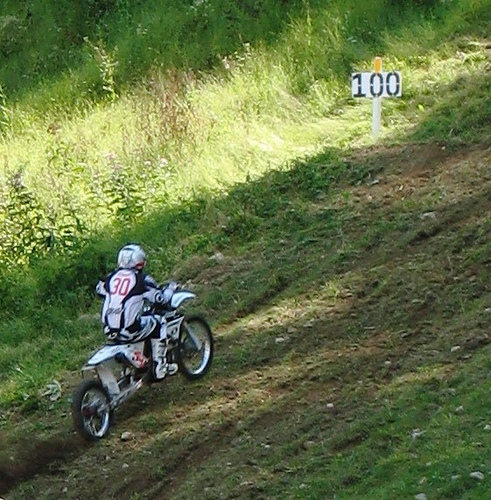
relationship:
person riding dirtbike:
[92, 243, 182, 382] [70, 272, 225, 446]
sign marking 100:
[349, 56, 406, 142] [349, 71, 404, 98]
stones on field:
[417, 207, 439, 223] [0, 123, 490, 498]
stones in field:
[417, 207, 439, 223] [0, 123, 490, 498]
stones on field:
[447, 338, 468, 354] [0, 123, 490, 498]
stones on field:
[469, 468, 489, 483] [0, 123, 490, 498]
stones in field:
[118, 431, 134, 441] [0, 123, 490, 498]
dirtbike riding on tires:
[70, 272, 225, 446] [71, 381, 112, 443]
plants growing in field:
[7, 170, 64, 272] [0, 123, 490, 498]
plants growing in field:
[103, 152, 142, 225] [0, 123, 490, 498]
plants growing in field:
[137, 151, 173, 198] [0, 123, 490, 498]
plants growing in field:
[202, 104, 282, 185] [0, 123, 490, 498]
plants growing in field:
[59, 189, 95, 240] [0, 123, 490, 498]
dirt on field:
[158, 465, 187, 484] [0, 123, 490, 498]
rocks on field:
[383, 359, 390, 365] [0, 123, 490, 498]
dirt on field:
[326, 401, 333, 409] [0, 123, 490, 498]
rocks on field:
[273, 334, 287, 344] [0, 123, 490, 498]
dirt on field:
[408, 237, 420, 250] [0, 123, 490, 498]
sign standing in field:
[349, 56, 406, 142] [1, 1, 490, 243]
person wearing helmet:
[92, 243, 182, 382] [115, 244, 147, 270]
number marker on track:
[349, 56, 406, 142] [4, 53, 490, 495]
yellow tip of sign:
[374, 57, 384, 73] [349, 56, 406, 142]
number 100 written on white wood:
[349, 71, 404, 98] [349, 56, 406, 142]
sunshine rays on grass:
[1, 39, 351, 244] [2, 5, 346, 159]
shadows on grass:
[2, 3, 451, 50] [2, 5, 346, 159]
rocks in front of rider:
[209, 251, 226, 265] [92, 243, 182, 382]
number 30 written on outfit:
[109, 277, 132, 297] [91, 268, 182, 383]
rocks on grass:
[383, 359, 390, 365] [296, 360, 490, 498]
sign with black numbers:
[349, 56, 406, 142] [349, 71, 404, 98]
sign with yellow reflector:
[349, 56, 406, 142] [373, 55, 381, 71]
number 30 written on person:
[109, 277, 132, 297] [92, 243, 182, 382]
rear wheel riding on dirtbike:
[71, 381, 112, 443] [70, 272, 225, 446]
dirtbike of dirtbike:
[70, 272, 225, 446] [70, 272, 225, 446]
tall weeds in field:
[6, 47, 317, 238] [0, 123, 490, 498]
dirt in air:
[3, 430, 83, 490] [3, 408, 82, 492]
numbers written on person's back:
[109, 277, 132, 297] [96, 271, 152, 340]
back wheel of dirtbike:
[71, 381, 112, 443] [70, 272, 225, 446]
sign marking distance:
[349, 56, 406, 142] [349, 71, 404, 98]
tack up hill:
[0, 123, 490, 498] [2, 1, 488, 498]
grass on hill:
[2, 5, 346, 159] [2, 1, 488, 498]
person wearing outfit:
[92, 243, 182, 382] [91, 268, 182, 383]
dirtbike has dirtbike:
[76, 287, 225, 446] [70, 272, 225, 446]